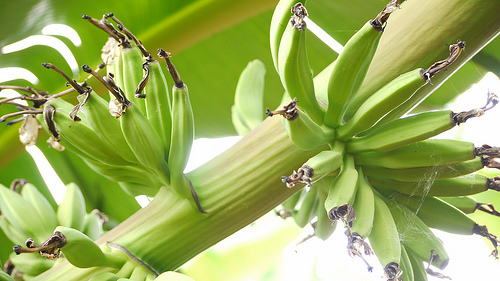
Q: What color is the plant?
A: Green.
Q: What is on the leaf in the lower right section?
A: Cobwebs.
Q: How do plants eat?
A: Photosynthesis.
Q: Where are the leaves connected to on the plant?
A: Stem.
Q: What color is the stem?
A: Pale green.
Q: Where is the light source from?
A: Sun.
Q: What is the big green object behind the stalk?
A: A leaf.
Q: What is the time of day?
A: Midday.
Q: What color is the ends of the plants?
A: Black.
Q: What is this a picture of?
A: A plant.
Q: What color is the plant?
A: Green.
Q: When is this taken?
A: During the daytime.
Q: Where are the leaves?
A: On the stalk.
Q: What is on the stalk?
A: Leaves.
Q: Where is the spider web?
A: In between leaves.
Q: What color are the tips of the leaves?
A: Brown.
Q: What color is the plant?
A: Green.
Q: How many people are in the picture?
A: 0.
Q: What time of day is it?
A: Daytime.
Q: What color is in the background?
A: Green.